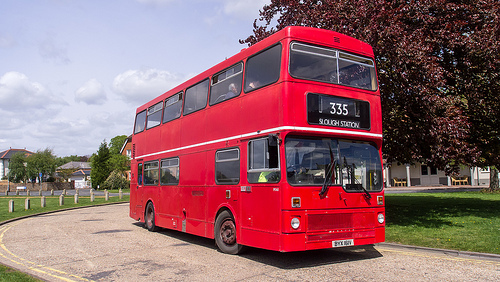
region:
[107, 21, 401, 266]
a double decker bus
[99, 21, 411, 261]
a red double decker bus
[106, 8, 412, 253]
a red bus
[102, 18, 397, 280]
a red bus on a street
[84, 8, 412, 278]
a double decker bus on a street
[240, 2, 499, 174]
a tree near the bus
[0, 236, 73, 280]
yellow lines on the road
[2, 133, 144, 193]
houses in the background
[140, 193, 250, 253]
tires on the bus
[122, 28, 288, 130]
windows on the bus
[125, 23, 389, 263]
A double decker bus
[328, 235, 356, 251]
A white license plate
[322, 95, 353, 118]
The number 335 on a bus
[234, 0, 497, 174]
Dark red leaves on a tree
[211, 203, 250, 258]
A black round tire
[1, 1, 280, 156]
White clouds in the sky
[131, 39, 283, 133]
Windows on side of the bus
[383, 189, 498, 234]
Shadow on the grass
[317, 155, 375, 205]
Two black windshield wipers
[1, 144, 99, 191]
Houses in the distance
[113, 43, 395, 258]
Red Double Decker Bus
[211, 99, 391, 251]
Red Double Decker Bus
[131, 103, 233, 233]
Red Double Decker Bus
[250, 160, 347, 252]
Red Double Decker Bus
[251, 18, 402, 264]
Red Double Decker Bus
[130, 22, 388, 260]
red double decker bus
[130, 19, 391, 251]
big red double decker bus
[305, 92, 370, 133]
black and white label of double decker bus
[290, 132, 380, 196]
large windshield of double decker bus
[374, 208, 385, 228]
small left front light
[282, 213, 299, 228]
small right front light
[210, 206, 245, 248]
left front black wheel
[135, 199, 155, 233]
black bag wheel of double decker bus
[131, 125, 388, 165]
white line of double decker bus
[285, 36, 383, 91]
windshield in second floor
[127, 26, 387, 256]
red double decker commercial bus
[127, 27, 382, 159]
top half of red double high bus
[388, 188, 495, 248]
green grassy area next to red bus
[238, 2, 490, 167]
red leaves on a large tree near a red bus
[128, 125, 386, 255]
bottom half of a double high red bus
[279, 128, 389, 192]
front windows of a double high red bus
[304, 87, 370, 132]
black destination sign with white text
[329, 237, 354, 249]
white license plate with black text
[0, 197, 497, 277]
gray road pavement under a red bus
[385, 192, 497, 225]
shadow of a tree in green grass